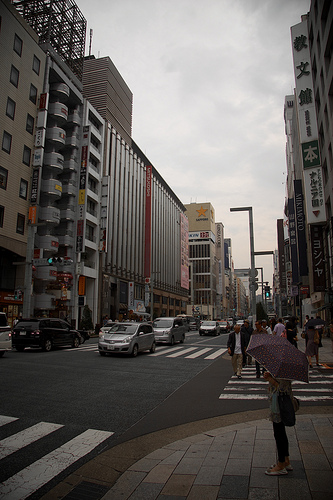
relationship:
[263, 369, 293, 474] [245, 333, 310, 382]
person holding umbrella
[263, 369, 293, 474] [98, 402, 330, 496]
person on a sidewalk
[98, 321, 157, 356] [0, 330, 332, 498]
cars on a ground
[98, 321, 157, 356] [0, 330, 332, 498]
cars on ground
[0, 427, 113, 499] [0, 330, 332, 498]
line on ground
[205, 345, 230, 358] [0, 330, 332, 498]
line on ground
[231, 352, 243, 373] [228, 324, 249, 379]
pants on man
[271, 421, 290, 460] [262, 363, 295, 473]
pants on woman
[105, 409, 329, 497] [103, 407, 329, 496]
bricks on ground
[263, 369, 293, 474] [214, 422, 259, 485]
person standing on sidewalk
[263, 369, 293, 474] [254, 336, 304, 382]
person with umbrella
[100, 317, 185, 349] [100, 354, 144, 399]
cars on the street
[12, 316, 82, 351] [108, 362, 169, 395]
vehicle driving down street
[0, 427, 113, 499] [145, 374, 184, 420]
line painted on road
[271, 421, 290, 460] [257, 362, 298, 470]
pants worn by woman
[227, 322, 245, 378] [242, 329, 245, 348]
man wearing coat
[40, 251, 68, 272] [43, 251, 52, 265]
signal showing light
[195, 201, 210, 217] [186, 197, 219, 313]
star on the building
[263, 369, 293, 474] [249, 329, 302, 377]
person standing with umbrella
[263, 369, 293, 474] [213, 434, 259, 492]
person standing on sidewalk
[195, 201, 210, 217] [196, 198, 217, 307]
star on the building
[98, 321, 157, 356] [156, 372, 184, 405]
cars on the street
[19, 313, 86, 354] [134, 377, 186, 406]
vehicle on the street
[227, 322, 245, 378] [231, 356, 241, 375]
man wearing pants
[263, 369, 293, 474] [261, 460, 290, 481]
person wearing shoes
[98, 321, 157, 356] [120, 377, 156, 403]
cars on the street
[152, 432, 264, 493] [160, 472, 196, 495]
walkway made of bricks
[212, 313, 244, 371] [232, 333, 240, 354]
man wearing shirt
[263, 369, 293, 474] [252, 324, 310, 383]
person holding umbrella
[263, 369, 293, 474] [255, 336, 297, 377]
person holding umbrella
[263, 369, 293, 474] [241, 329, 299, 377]
person obfuscated by an umbrella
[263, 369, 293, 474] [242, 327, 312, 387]
person holds umbrella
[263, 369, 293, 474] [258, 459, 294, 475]
person wears shoes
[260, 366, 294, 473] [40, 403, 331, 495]
person standing on corner sidewalk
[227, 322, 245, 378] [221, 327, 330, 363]
man walking on sidewalk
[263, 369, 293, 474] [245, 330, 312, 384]
person standing under umbrella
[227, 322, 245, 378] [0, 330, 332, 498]
man crossing ground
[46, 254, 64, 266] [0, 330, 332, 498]
signal hanging over ground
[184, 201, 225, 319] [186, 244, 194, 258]
window on building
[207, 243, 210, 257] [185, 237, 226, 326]
window on building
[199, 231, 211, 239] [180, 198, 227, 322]
window on building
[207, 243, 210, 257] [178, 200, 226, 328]
window on building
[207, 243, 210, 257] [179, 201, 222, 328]
window on building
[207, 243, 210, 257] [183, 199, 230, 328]
window on building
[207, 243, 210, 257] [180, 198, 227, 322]
window on building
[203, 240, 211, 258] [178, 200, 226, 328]
window on building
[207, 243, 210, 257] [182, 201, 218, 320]
window on building